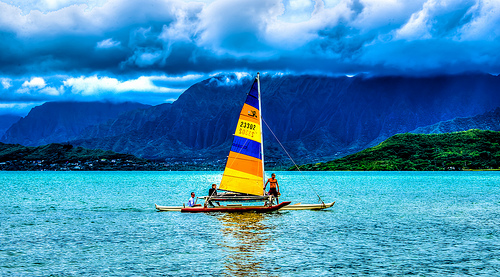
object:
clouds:
[0, 0, 500, 74]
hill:
[290, 107, 500, 172]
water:
[1, 167, 500, 277]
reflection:
[218, 210, 266, 277]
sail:
[215, 72, 266, 196]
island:
[0, 68, 499, 172]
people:
[209, 184, 218, 196]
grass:
[383, 130, 498, 170]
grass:
[0, 144, 139, 160]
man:
[188, 192, 202, 207]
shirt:
[209, 188, 217, 197]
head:
[271, 173, 275, 178]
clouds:
[0, 75, 207, 105]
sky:
[0, 0, 497, 73]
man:
[263, 173, 279, 206]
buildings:
[20, 159, 57, 171]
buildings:
[56, 160, 84, 171]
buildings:
[112, 159, 148, 170]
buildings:
[144, 161, 191, 168]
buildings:
[185, 159, 217, 172]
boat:
[199, 191, 280, 201]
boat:
[181, 201, 292, 213]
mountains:
[0, 72, 500, 167]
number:
[240, 122, 256, 130]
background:
[0, 0, 500, 170]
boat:
[155, 72, 335, 211]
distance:
[0, 73, 500, 130]